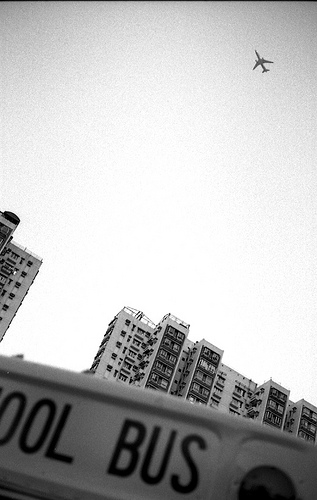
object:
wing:
[261, 56, 273, 65]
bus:
[0, 352, 316, 498]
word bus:
[108, 419, 208, 493]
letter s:
[171, 433, 207, 494]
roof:
[122, 306, 153, 329]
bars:
[120, 306, 153, 318]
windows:
[138, 329, 155, 344]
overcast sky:
[0, 3, 317, 371]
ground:
[251, 115, 292, 194]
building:
[1, 206, 48, 354]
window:
[166, 324, 175, 337]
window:
[197, 360, 208, 372]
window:
[25, 260, 32, 269]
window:
[272, 389, 277, 400]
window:
[151, 360, 166, 370]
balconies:
[246, 385, 267, 418]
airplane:
[251, 47, 274, 73]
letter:
[2, 383, 226, 496]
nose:
[252, 46, 263, 56]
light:
[234, 461, 296, 500]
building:
[0, 205, 317, 450]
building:
[89, 296, 306, 432]